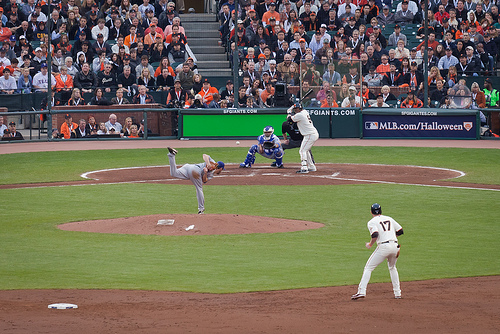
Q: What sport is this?
A: Baseball.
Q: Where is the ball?
A: In the air.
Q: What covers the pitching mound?
A: Dirt.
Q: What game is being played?
A: Baseball.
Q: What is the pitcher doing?
A: Throwing the ball.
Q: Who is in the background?
A: Fans.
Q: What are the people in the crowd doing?
A: Watching the game.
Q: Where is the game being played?
A: Baseball field.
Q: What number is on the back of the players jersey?
A: 17.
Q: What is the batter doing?
A: About to hit the ball.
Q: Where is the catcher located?
A: Behind the batter.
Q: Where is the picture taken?
A: A baseball field.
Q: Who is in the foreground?
A: Players.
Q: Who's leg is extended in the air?
A: The pitcher.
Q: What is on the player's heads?
A: Helmets.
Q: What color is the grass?
A: Green.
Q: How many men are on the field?
A: Five.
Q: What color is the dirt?
A: Brown.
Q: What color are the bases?
A: White.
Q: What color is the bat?
A: Black.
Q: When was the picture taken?
A: Daytime.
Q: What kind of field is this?
A: Baseball field.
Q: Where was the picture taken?
A: At a ballgame.